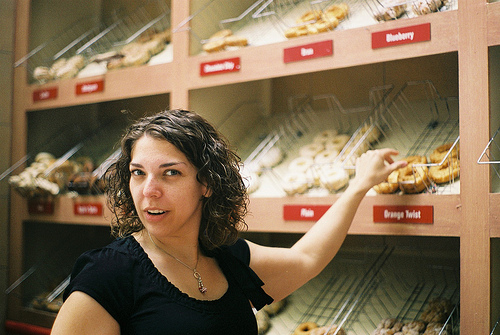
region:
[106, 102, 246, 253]
Woman looking at the camera.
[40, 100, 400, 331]
Woman reaching for something in the background.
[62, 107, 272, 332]
Woman wearing a black shirt and necklace.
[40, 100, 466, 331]
Woman reaching for an Orange Twist bagel.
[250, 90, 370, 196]
Wire bin full of Plain bagels.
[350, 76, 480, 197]
Wire bin full of Orange Twist bagels.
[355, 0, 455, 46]
Wire bin full of Blueberry bagels.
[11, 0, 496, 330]
Wooden shelves, with wire bins full of different types of bagels.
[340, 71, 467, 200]
Hand reaching for a bagel.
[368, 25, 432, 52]
red sign with white writing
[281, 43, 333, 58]
red sign with white writing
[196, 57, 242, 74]
red sign with white writing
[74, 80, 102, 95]
red sign with white writing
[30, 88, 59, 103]
red sign with white writing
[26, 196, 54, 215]
red sign with white writing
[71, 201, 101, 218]
red sign with white writing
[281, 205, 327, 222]
red sign with white writing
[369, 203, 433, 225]
red sign with white writing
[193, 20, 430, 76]
red signs with white writing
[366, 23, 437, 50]
label on the shelf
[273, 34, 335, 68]
label on the shelf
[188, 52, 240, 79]
label on the shelf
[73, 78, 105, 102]
label on the shelf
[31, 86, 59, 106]
label on the shelf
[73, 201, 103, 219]
label on the shelf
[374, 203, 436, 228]
label on the shelf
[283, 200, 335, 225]
label on the shelf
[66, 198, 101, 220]
label on the shelf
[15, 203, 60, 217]
label on the shelf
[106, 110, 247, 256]
woman with brown curly hair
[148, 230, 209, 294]
woman wearing a silver pendant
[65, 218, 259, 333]
woman wearing a black shirt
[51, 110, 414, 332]
a woman reaching for a doughnut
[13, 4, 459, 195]
a selection of doughnuts on metal trays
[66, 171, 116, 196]
doughnuts with chocolate glaze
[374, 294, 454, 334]
doughnuts on a metal tray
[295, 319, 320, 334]
a plain doughnut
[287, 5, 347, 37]
doughnuts with a honey glaze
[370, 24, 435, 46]
a red panel with white writing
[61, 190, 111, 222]
red tag on shelf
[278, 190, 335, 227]
red tag on shelf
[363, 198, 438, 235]
red tag on shelf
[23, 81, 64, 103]
red tag on shelf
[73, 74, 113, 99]
red tag on shelf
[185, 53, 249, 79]
red tag on shelf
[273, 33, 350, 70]
red tag on shelf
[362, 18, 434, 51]
red tag on shelf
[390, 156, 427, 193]
plain cake donut in rack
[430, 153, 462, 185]
plain cake donut in rack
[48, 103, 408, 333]
woman reaches for bagel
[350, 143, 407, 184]
hand belongs to woman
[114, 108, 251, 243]
head belongs to woman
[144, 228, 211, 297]
necklace is worn by woman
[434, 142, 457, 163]
bagel is next ot bagel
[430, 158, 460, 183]
bagel is next ot bagel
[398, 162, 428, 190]
bagel is next ot bagel